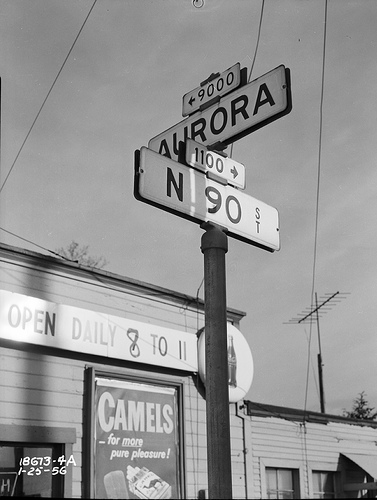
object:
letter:
[163, 166, 185, 203]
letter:
[200, 184, 223, 216]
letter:
[224, 193, 244, 225]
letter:
[254, 207, 262, 219]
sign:
[134, 137, 280, 252]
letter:
[253, 221, 262, 235]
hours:
[120, 322, 190, 369]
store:
[0, 245, 363, 494]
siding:
[0, 401, 83, 423]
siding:
[0, 355, 85, 368]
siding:
[0, 384, 83, 408]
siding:
[0, 267, 163, 290]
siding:
[183, 458, 207, 472]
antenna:
[287, 286, 348, 416]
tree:
[344, 392, 372, 425]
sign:
[125, 68, 297, 262]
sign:
[123, 141, 286, 256]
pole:
[195, 273, 204, 296]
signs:
[182, 138, 248, 189]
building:
[0, 244, 376, 498]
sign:
[114, 113, 315, 252]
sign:
[137, 62, 313, 175]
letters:
[7, 302, 190, 363]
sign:
[2, 289, 254, 370]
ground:
[290, 133, 344, 183]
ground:
[329, 86, 371, 116]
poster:
[77, 360, 188, 500]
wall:
[264, 427, 297, 462]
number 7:
[127, 326, 140, 350]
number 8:
[125, 325, 143, 359]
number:
[11, 438, 79, 481]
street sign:
[180, 61, 246, 118]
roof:
[245, 399, 375, 428]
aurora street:
[145, 64, 293, 177]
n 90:
[131, 146, 285, 257]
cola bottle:
[226, 333, 239, 389]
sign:
[193, 318, 254, 407]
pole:
[201, 69, 233, 498]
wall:
[233, 417, 244, 496]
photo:
[0, 2, 374, 497]